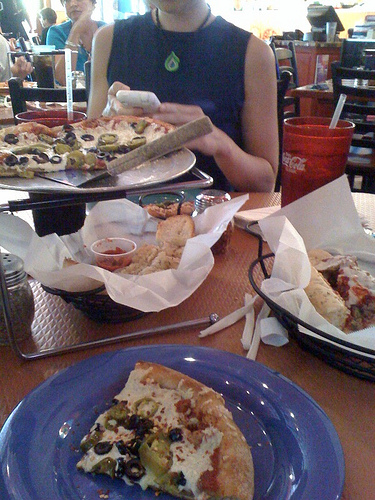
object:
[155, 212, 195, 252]
bread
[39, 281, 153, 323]
basket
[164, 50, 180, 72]
pendant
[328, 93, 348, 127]
straw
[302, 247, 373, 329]
pizza slice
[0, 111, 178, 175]
pizza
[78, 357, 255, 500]
pizza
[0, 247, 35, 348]
pepper shaker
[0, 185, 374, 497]
table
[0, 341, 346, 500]
plate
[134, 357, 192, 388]
crust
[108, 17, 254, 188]
top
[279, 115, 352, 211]
cup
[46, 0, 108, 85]
woman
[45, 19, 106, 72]
shirt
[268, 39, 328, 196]
chairs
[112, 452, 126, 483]
olives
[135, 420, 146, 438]
olives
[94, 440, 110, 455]
olives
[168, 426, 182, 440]
olives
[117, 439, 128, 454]
olives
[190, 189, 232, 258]
pepper flakes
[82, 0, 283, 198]
girl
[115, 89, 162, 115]
cell phone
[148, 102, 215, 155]
hands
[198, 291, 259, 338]
wrapper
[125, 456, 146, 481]
black olives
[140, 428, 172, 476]
jalapenos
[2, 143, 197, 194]
serving tray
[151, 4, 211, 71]
necklace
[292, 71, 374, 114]
table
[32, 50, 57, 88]
cup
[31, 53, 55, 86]
soft drink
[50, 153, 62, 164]
olives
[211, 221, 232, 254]
pepper